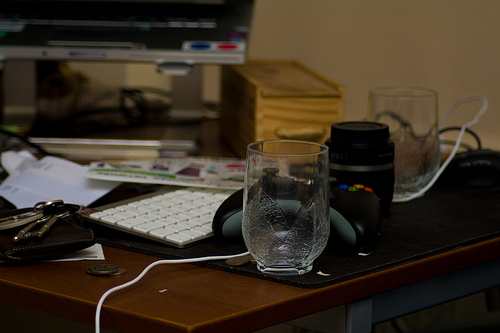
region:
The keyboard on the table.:
[92, 192, 256, 243]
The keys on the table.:
[10, 192, 94, 246]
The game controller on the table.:
[213, 165, 378, 259]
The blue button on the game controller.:
[342, 180, 353, 190]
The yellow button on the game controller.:
[355, 179, 363, 186]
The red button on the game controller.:
[362, 182, 376, 189]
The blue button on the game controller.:
[340, 173, 350, 187]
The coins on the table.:
[86, 253, 130, 275]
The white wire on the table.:
[85, 89, 497, 331]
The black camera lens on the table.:
[323, 116, 401, 206]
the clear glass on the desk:
[243, 140, 328, 276]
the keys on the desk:
[1, 198, 81, 239]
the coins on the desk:
[86, 262, 125, 274]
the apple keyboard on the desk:
[80, 184, 240, 246]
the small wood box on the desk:
[218, 59, 345, 164]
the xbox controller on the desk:
[211, 172, 381, 249]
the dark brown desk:
[0, 117, 499, 331]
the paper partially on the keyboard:
[88, 154, 263, 191]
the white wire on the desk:
[94, 93, 488, 331]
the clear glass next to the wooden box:
[367, 83, 439, 198]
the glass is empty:
[237, 137, 339, 287]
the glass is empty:
[234, 118, 331, 314]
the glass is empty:
[240, 129, 324, 310]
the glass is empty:
[231, 136, 327, 274]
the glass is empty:
[233, 132, 327, 287]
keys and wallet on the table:
[9, 180, 104, 289]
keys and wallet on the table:
[7, 189, 94, 275]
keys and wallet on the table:
[12, 182, 99, 285]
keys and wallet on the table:
[10, 191, 95, 285]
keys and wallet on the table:
[10, 182, 87, 262]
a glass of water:
[239, 131, 334, 278]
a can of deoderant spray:
[320, 113, 398, 268]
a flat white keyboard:
[92, 163, 229, 258]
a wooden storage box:
[219, 53, 353, 171]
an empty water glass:
[363, 81, 445, 188]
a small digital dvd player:
[30, 88, 195, 152]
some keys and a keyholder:
[0, 191, 91, 259]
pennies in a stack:
[82, 261, 133, 283]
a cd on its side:
[83, 141, 283, 202]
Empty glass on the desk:
[242, 139, 329, 281]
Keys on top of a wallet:
[1, 199, 96, 266]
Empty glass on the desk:
[366, 81, 443, 195]